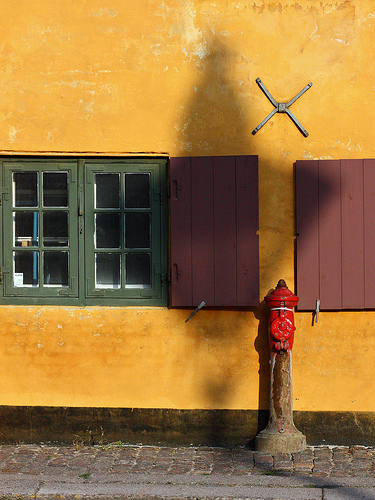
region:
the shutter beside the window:
[164, 154, 258, 302]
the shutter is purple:
[170, 151, 266, 307]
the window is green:
[0, 160, 169, 303]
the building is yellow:
[1, 1, 371, 415]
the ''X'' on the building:
[241, 69, 322, 141]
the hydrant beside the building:
[262, 276, 308, 351]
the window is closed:
[3, 162, 158, 306]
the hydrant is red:
[263, 276, 300, 348]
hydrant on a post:
[255, 278, 305, 459]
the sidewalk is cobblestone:
[9, 433, 373, 495]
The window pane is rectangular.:
[9, 168, 40, 208]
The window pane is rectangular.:
[39, 170, 71, 209]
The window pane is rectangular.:
[10, 208, 40, 248]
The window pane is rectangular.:
[39, 206, 70, 249]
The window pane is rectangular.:
[10, 246, 41, 290]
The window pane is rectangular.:
[38, 246, 71, 289]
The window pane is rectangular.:
[92, 249, 124, 290]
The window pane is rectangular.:
[122, 249, 155, 291]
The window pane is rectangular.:
[90, 208, 124, 251]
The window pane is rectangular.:
[121, 208, 156, 250]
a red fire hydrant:
[264, 280, 299, 351]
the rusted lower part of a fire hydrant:
[253, 350, 307, 453]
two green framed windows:
[1, 158, 166, 306]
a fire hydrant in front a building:
[254, 277, 308, 451]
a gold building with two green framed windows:
[0, 0, 370, 444]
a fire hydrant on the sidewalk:
[1, 352, 373, 498]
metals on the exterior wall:
[250, 75, 312, 137]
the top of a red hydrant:
[265, 278, 297, 301]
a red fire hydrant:
[253, 278, 306, 454]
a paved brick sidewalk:
[0, 444, 373, 498]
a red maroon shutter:
[169, 156, 259, 309]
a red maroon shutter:
[292, 158, 373, 309]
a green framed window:
[0, 157, 166, 306]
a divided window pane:
[125, 252, 149, 287]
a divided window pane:
[94, 252, 118, 288]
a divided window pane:
[93, 211, 119, 247]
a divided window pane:
[96, 174, 117, 206]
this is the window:
[10, 161, 160, 288]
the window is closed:
[22, 170, 153, 270]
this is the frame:
[149, 160, 163, 170]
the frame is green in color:
[129, 289, 146, 302]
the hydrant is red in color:
[258, 283, 301, 349]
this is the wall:
[121, 37, 237, 104]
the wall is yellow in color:
[99, 21, 197, 97]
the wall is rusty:
[149, 15, 223, 74]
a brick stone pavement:
[4, 433, 371, 496]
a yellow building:
[16, 16, 362, 337]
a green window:
[0, 149, 190, 320]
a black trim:
[0, 398, 371, 460]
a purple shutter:
[160, 149, 373, 327]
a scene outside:
[5, 97, 371, 444]